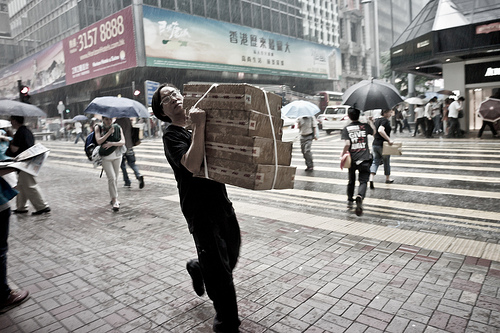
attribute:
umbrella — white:
[278, 97, 316, 117]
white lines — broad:
[399, 135, 499, 236]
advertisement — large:
[222, 24, 437, 76]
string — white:
[191, 78, 279, 191]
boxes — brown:
[380, 143, 402, 157]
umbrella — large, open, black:
[350, 70, 410, 122]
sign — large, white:
[137, 4, 357, 73]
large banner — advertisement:
[61, 12, 134, 70]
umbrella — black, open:
[82, 95, 154, 121]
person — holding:
[5, 120, 59, 241]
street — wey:
[2, 94, 497, 331]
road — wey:
[29, 126, 498, 247]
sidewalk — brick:
[69, 226, 158, 323]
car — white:
[327, 105, 347, 131]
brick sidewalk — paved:
[4, 172, 499, 332]